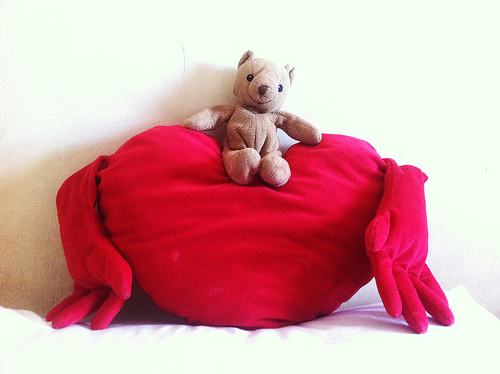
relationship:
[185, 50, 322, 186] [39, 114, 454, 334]
bear sitting on heart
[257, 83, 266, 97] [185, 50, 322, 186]
nose on bear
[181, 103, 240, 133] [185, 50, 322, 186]
arm on bear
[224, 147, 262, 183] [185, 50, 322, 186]
leg on bear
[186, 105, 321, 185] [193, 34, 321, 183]
body on bear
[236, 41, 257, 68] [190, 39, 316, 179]
ear on bear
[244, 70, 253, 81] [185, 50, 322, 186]
eye on bear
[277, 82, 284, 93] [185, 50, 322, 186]
eye on bear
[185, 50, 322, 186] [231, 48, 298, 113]
bear has head